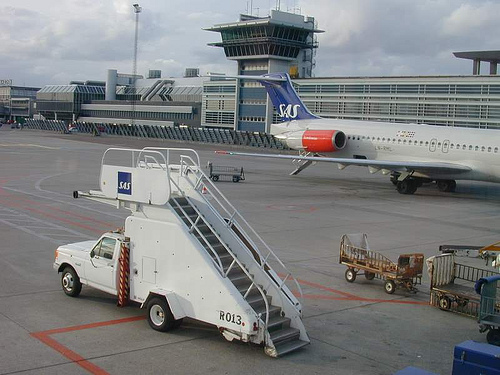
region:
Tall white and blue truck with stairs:
[36, 131, 318, 366]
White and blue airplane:
[232, 55, 497, 200]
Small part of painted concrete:
[8, 315, 58, 347]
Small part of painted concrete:
[52, 315, 102, 343]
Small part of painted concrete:
[93, 302, 153, 337]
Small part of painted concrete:
[59, 349, 89, 369]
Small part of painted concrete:
[363, 283, 430, 320]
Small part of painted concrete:
[300, 284, 349, 307]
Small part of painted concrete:
[41, 195, 88, 228]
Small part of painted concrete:
[10, 186, 40, 241]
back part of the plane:
[294, 113, 361, 166]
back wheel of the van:
[136, 290, 195, 339]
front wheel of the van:
[51, 267, 97, 301]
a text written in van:
[202, 302, 262, 329]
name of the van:
[208, 301, 283, 344]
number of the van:
[209, 290, 269, 339]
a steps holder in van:
[104, 155, 324, 365]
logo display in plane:
[258, 88, 324, 123]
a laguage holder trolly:
[326, 225, 498, 318]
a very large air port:
[68, 18, 496, 133]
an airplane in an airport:
[199, 52, 499, 193]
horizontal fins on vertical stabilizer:
[201, 68, 302, 90]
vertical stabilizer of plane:
[257, 68, 315, 120]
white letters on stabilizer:
[271, 88, 310, 124]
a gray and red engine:
[269, 122, 349, 157]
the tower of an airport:
[196, 3, 327, 83]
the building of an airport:
[4, 8, 498, 165]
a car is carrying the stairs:
[36, 129, 316, 356]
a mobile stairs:
[154, 163, 322, 360]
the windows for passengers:
[344, 128, 496, 160]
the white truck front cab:
[52, 233, 129, 298]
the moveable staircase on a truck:
[77, 145, 317, 355]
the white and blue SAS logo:
[118, 173, 134, 193]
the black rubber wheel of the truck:
[60, 267, 78, 294]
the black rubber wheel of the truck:
[147, 303, 169, 331]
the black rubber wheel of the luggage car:
[342, 265, 352, 282]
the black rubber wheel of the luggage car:
[383, 278, 395, 294]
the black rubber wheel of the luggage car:
[437, 293, 445, 309]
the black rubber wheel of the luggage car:
[364, 268, 373, 278]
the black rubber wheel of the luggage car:
[455, 293, 470, 303]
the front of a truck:
[53, 235, 115, 294]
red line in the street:
[37, 332, 74, 356]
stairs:
[272, 303, 286, 350]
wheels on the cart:
[382, 280, 397, 292]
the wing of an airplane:
[282, 146, 375, 172]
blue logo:
[115, 173, 133, 194]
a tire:
[145, 303, 167, 325]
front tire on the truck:
[56, 270, 78, 295]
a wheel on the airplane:
[391, 175, 416, 191]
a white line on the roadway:
[32, 177, 62, 194]